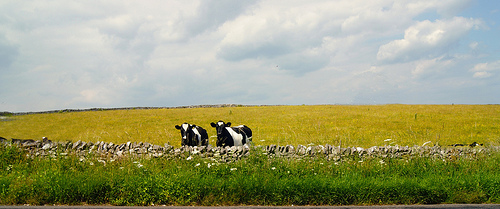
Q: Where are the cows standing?
A: In a field.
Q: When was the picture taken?
A: Daytime.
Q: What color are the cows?
A: Black and white.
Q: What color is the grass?
A: Green.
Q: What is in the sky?
A: Clouds.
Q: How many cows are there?
A: Two.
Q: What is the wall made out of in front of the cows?
A: Rocks.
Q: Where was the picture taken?
A: In a field.